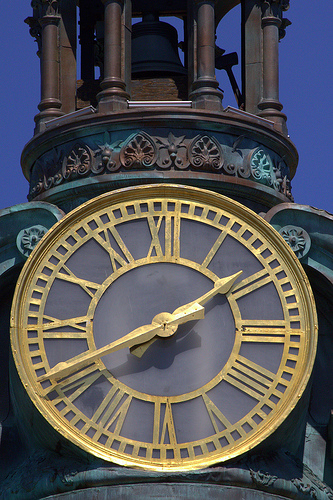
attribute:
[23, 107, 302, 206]
copper — blue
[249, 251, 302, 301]
numeral — II, roman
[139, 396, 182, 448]
roman numeral — VI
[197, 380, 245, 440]
numeral — roman, V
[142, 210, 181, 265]
numeral twelve — roman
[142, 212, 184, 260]
roman numeral — gold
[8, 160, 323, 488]
clock — brown and grey, large, gold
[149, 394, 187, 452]
number six — roman numeral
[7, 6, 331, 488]
bell tower — whole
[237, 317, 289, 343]
three — roman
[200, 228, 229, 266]
roman numeral — I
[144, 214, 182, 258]
roman numeral — XII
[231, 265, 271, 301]
roman numeral — II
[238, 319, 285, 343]
roman numeral — III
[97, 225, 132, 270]
roman numeral — XI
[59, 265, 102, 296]
roman numeral — X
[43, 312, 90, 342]
roman numeral — IX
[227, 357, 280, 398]
roman numeral — V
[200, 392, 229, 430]
roman numeral — VI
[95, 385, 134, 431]
roman numeral — VII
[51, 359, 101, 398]
roman numeral — VIII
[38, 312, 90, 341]
nine — roman numeral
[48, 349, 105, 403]
numeral eight — roman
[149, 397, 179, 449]
roman numeral — gold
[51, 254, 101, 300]
roman numeral — X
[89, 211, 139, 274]
roman numeral — XI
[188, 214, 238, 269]
roman numeral — gold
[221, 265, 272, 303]
roman numeral — gold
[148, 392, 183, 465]
roman numeral — gold, VI